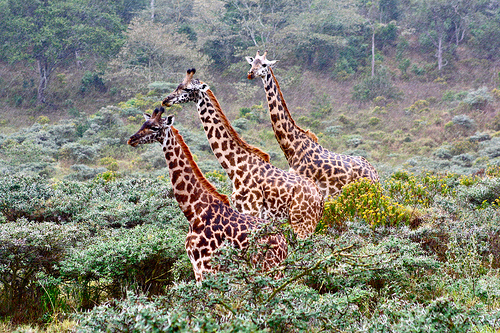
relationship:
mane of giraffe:
[269, 79, 324, 149] [241, 45, 416, 218]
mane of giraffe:
[269, 79, 324, 149] [163, 72, 338, 221]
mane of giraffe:
[269, 79, 324, 149] [116, 112, 296, 295]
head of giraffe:
[158, 61, 213, 114] [150, 60, 335, 277]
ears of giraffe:
[143, 111, 175, 125] [128, 105, 288, 287]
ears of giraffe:
[196, 81, 212, 91] [162, 67, 325, 242]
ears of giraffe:
[243, 53, 280, 67] [245, 50, 382, 200]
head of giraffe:
[127, 105, 173, 145] [128, 105, 288, 287]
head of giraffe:
[161, 68, 199, 108] [162, 67, 325, 242]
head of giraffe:
[241, 47, 279, 82] [245, 50, 382, 200]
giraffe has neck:
[119, 69, 326, 222] [124, 49, 296, 209]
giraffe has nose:
[160, 67, 343, 237] [247, 67, 254, 79]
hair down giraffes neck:
[153, 142, 236, 186] [257, 68, 316, 156]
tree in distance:
[367, 15, 397, 81] [82, 51, 442, 219]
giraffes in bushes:
[124, 49, 387, 286] [165, 184, 484, 331]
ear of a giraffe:
[266, 59, 278, 71] [245, 50, 382, 200]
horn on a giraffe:
[252, 48, 277, 60] [152, 138, 216, 276]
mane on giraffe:
[201, 87, 270, 166] [154, 71, 319, 241]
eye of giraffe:
[259, 60, 270, 70] [245, 50, 382, 200]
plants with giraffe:
[0, 213, 185, 328] [128, 105, 288, 287]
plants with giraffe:
[0, 213, 185, 328] [162, 67, 325, 242]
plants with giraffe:
[0, 213, 185, 328] [245, 50, 382, 200]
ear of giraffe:
[160, 112, 178, 130] [124, 98, 300, 279]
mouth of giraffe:
[128, 127, 157, 146] [117, 112, 241, 271]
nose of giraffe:
[126, 131, 142, 145] [117, 112, 241, 271]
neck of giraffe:
[160, 143, 208, 213] [126, 101, 272, 283]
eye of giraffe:
[260, 60, 266, 68] [239, 43, 389, 209]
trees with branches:
[340, 3, 478, 81] [372, 23, 404, 44]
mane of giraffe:
[268, 67, 318, 144] [239, 43, 389, 209]